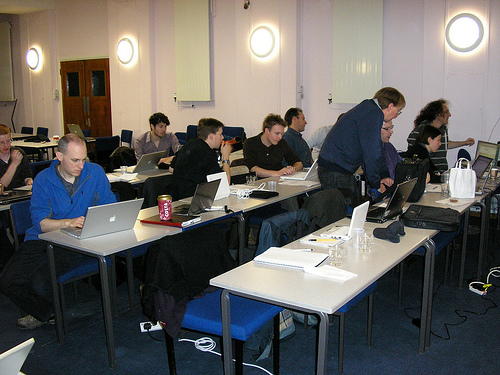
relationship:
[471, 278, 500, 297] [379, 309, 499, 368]
cables on floor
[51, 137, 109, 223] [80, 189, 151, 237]
man using laptop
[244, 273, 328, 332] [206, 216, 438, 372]
top of desk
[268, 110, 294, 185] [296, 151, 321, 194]
man using laptop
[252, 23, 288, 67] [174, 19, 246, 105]
light on wall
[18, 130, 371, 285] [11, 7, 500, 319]
desk in room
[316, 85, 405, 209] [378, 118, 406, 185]
man helping person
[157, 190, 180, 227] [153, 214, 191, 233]
can on book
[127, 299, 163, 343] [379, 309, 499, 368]
powerstrip on floor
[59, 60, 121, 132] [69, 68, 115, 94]
doors have windows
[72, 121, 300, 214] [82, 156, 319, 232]
kids using laptops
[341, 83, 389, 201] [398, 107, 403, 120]
man wearing glasses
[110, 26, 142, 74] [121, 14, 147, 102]
light on wall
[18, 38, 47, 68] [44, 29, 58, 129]
light on wall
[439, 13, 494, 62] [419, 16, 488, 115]
light on wall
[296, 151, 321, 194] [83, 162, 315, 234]
laptop on top of table